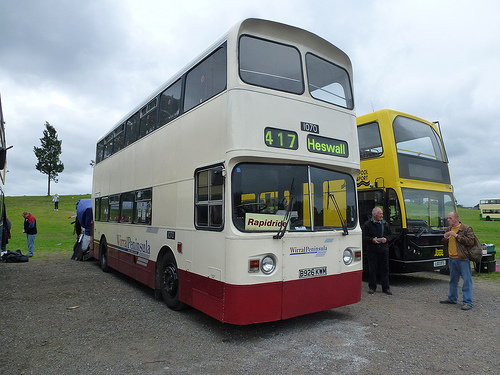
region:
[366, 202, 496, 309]
Two men by city bus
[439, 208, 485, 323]
Man wearing blue jeans and yellow shirt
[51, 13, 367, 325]
Two story transportation bus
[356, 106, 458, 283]
Yellow and black bus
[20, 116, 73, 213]
Green tall tree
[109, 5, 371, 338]
Transportation bus is being with red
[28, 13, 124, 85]
Dark gray clouds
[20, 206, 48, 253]
Person wearing red and black jacket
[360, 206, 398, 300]
Man wearing dark top and pants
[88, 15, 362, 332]
Tan and red bus with two lights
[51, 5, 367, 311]
bus in a parking lot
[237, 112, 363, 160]
sign on a bus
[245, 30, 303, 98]
window on a bus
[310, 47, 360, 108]
window on a bus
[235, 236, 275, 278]
light on a bus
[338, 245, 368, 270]
light on a bus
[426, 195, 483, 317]
man wearing brown jacket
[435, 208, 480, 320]
man wearing yellow shirt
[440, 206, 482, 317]
man wearing blue jeans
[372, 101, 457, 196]
bus in parking lot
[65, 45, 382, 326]
The bus is white.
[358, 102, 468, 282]
The bus is yellow.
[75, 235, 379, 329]
The bottom of the bus is red.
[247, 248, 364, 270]
The lights are off.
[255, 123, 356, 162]
The lights are yellow.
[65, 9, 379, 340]
The bus is a double decker.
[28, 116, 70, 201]
The tree is leafy.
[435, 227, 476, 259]
He has a yellow shirt.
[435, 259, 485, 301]
He has jeans on.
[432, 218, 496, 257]
He has a brown jacket.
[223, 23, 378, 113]
top part of the bus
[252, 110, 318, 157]
number of the bus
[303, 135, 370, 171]
destination of the bus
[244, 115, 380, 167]
display on the top of bus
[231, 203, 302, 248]
a board in the bus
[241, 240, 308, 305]
light of the bus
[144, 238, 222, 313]
wheel of the bus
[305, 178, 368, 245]
mirror cleaner of th ebus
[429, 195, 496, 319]
a man standing in road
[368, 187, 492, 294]
two men standing beside bus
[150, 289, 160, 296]
part of a wheel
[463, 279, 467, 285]
part of a jeans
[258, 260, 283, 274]
part of a light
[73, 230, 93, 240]
part of a lawn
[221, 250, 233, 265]
edge of a bus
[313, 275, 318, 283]
part of a plate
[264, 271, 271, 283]
part of a light